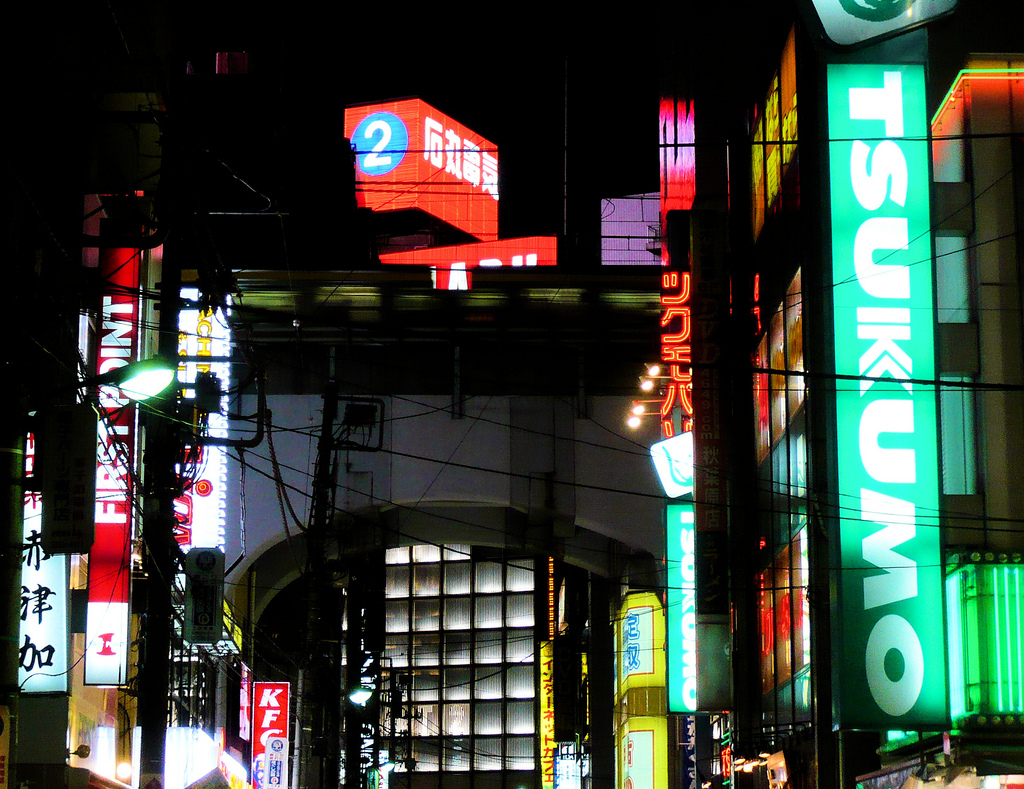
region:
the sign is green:
[824, 64, 952, 741]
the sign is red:
[353, 104, 515, 251]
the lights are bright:
[0, 3, 1021, 784]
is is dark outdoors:
[5, 0, 1020, 785]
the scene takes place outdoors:
[2, 22, 1018, 785]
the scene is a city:
[5, 9, 1017, 782]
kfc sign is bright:
[249, 682, 294, 787]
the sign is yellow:
[616, 597, 667, 778]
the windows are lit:
[373, 528, 538, 785]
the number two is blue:
[345, 121, 400, 175]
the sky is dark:
[125, 5, 743, 296]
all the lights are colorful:
[40, 98, 958, 787]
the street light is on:
[36, 266, 242, 478]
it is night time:
[96, 26, 698, 255]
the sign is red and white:
[219, 646, 284, 751]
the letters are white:
[225, 662, 299, 733]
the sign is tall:
[769, 35, 960, 729]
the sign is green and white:
[781, 1, 953, 739]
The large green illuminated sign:
[796, 82, 964, 740]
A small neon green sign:
[932, 538, 1015, 717]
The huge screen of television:
[717, 86, 848, 745]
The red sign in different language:
[657, 263, 709, 434]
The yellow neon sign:
[593, 582, 688, 786]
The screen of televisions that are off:
[374, 540, 537, 779]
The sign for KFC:
[238, 680, 297, 779]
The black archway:
[203, 387, 672, 622]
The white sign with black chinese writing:
[4, 412, 72, 694]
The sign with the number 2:
[337, 95, 524, 235]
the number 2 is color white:
[325, 86, 510, 251]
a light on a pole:
[54, 342, 184, 453]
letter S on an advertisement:
[833, 130, 916, 217]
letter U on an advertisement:
[844, 210, 916, 303]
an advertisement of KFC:
[240, 670, 296, 787]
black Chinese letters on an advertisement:
[15, 500, 75, 704]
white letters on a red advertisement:
[409, 114, 510, 203]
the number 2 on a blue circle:
[347, 110, 415, 180]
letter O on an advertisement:
[850, 604, 929, 722]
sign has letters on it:
[848, 86, 956, 703]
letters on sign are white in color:
[827, 60, 946, 709]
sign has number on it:
[336, 110, 417, 186]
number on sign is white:
[362, 98, 391, 209]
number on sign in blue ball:
[345, 119, 432, 186]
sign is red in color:
[248, 677, 297, 761]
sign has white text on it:
[254, 683, 294, 761]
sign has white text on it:
[403, 110, 560, 227]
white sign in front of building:
[11, 422, 69, 697]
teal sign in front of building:
[824, 65, 947, 729]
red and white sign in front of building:
[89, 248, 132, 686]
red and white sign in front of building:
[248, 683, 281, 783]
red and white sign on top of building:
[340, 95, 502, 242]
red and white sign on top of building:
[373, 235, 555, 290]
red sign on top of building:
[658, 234, 699, 440]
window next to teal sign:
[938, 236, 969, 325]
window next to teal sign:
[934, 111, 967, 182]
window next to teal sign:
[940, 372, 973, 495]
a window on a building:
[380, 566, 410, 601]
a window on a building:
[405, 566, 435, 602]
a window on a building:
[432, 552, 470, 600]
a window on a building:
[480, 563, 501, 592]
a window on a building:
[506, 561, 532, 594]